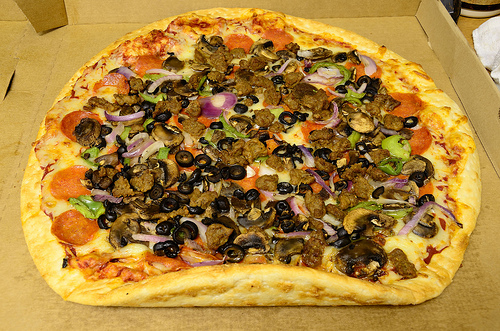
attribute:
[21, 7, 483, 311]
food — delicious, hot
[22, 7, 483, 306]
pizza — tasty, below, spicy, big, yellow, a, folded, round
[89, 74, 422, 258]
design — beautiful, cute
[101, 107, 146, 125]
onion — piece, red, purple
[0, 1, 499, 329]
box — empty, cardboard, open, brown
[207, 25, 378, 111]
pieces — decorative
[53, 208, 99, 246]
pepperoni — curling, piece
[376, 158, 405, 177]
peppers — green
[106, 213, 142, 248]
mushrooms — slices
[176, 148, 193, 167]
olive — slice, black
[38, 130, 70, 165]
mozzarella — melted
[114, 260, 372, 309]
crust — folded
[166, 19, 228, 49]
spices — brown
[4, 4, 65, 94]
cardboard — brown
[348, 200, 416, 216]
leaf — basil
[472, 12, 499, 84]
towel — white